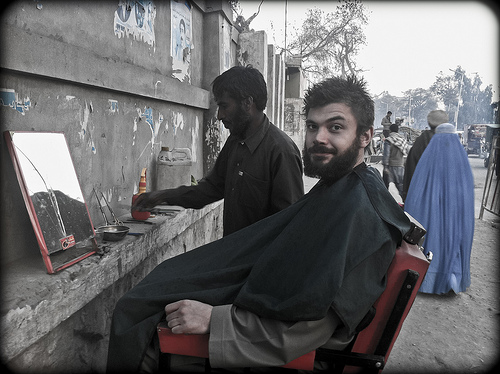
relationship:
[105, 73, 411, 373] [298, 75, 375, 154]
man has hair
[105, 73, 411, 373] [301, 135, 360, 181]
man has beard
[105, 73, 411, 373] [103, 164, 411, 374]
man wearing cape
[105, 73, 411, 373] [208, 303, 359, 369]
man wearing shirt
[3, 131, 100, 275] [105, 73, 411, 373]
mirror in front of man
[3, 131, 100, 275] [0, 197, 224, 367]
mirror on shelf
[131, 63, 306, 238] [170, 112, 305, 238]
man has shirt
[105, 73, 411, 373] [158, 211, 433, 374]
man sits on chair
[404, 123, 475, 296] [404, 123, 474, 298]
woman has headscarf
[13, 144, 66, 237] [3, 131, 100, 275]
crack in mirror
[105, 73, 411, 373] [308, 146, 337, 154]
man has mustache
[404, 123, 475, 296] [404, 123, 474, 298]
woman in headscarf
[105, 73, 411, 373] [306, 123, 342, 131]
man has eyes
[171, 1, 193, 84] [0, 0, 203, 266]
advertisement on wall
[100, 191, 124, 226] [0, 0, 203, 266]
scissors leaning against wall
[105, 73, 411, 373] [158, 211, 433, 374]
man sitting in a chair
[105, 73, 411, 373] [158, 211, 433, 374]
man sitting in chair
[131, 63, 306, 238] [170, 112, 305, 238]
man wearing shirt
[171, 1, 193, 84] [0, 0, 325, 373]
advertisement on building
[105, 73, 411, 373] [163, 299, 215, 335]
man has hand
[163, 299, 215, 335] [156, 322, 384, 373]
hand resting on arm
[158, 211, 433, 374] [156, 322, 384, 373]
chair has arm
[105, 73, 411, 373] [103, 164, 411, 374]
man has cape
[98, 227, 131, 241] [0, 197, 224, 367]
wash bowl on shelf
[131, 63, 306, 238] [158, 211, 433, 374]
man behind chair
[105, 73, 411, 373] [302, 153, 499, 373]
man on street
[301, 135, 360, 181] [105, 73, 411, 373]
beard on man